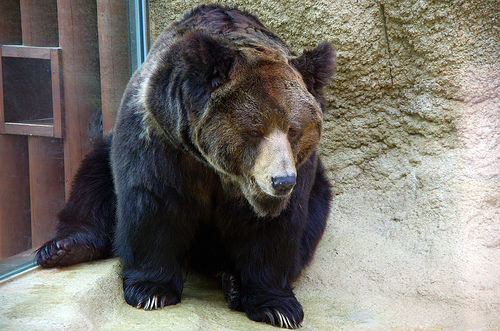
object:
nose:
[273, 177, 297, 189]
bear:
[34, 4, 332, 328]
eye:
[249, 129, 262, 137]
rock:
[146, 0, 498, 330]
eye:
[290, 128, 300, 137]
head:
[175, 36, 337, 218]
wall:
[1, 3, 145, 284]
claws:
[122, 280, 182, 311]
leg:
[114, 134, 192, 310]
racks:
[0, 0, 149, 291]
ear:
[177, 29, 237, 78]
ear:
[290, 39, 336, 98]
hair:
[32, 2, 333, 330]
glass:
[0, 0, 140, 287]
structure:
[0, 9, 100, 134]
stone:
[369, 112, 469, 305]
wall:
[149, 6, 484, 316]